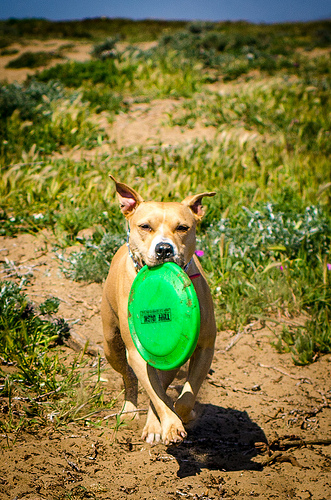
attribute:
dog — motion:
[94, 171, 221, 453]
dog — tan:
[72, 173, 263, 412]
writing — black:
[139, 307, 170, 323]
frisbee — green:
[125, 260, 200, 372]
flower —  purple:
[192, 246, 209, 258]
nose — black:
[154, 241, 173, 262]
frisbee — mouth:
[124, 267, 209, 380]